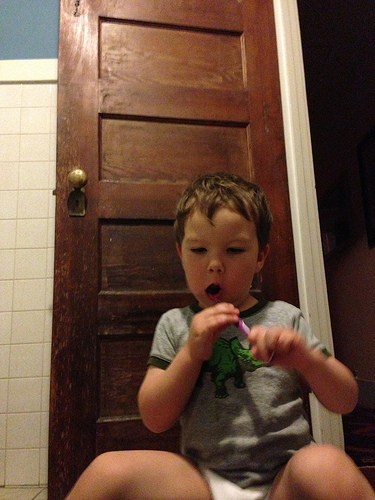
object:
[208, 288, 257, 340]
toothbrush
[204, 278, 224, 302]
kid's mouth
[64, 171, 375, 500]
kid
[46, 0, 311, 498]
door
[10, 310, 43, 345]
tile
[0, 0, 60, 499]
wall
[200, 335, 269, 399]
dinosaur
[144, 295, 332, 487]
shirt